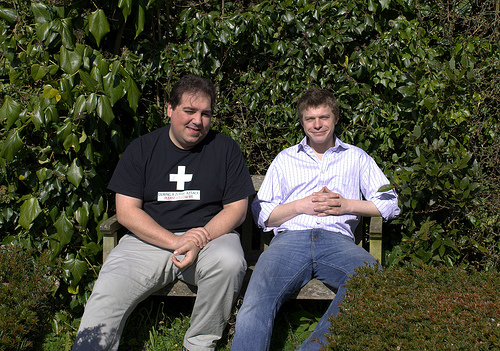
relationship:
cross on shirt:
[164, 162, 197, 192] [133, 138, 232, 206]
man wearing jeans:
[108, 74, 252, 304] [104, 262, 140, 310]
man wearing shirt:
[108, 74, 252, 304] [133, 138, 232, 206]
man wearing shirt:
[272, 78, 393, 226] [272, 156, 382, 190]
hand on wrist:
[188, 226, 213, 248] [175, 237, 185, 249]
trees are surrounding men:
[237, 23, 406, 86] [82, 61, 416, 349]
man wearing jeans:
[272, 78, 393, 226] [273, 245, 354, 314]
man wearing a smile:
[108, 74, 252, 304] [189, 128, 205, 135]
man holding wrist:
[108, 74, 252, 304] [175, 237, 185, 249]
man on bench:
[108, 74, 252, 304] [251, 176, 260, 249]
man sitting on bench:
[108, 74, 252, 304] [251, 176, 260, 249]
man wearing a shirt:
[108, 74, 252, 304] [133, 138, 232, 206]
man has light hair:
[272, 78, 393, 226] [296, 89, 338, 106]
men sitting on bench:
[82, 61, 416, 349] [251, 176, 260, 249]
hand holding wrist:
[188, 226, 213, 248] [175, 237, 185, 249]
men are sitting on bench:
[82, 61, 416, 349] [251, 176, 260, 249]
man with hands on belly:
[108, 74, 252, 304] [171, 216, 205, 238]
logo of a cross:
[156, 163, 207, 206] [164, 162, 197, 192]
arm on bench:
[99, 218, 113, 242] [251, 176, 260, 249]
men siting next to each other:
[82, 61, 416, 349] [146, 72, 377, 195]